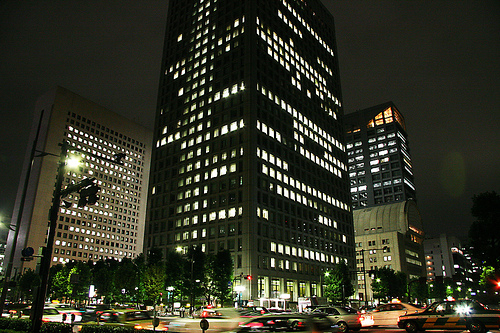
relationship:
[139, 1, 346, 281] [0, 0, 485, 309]
windows on buildings/windows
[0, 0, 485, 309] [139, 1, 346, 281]
buildings/windows has windows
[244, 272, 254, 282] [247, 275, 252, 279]
stop light with a red light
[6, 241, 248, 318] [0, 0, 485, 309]
trees outside of a buildings/windows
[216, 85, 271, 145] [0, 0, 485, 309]
windows on buildings/windows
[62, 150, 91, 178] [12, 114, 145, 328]
light on a pole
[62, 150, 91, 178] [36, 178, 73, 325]
light on a metal pole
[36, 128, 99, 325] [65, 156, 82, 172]
metal pole with a light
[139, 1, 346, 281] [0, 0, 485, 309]
windows of buildings/windows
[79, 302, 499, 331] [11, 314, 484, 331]
cars on street